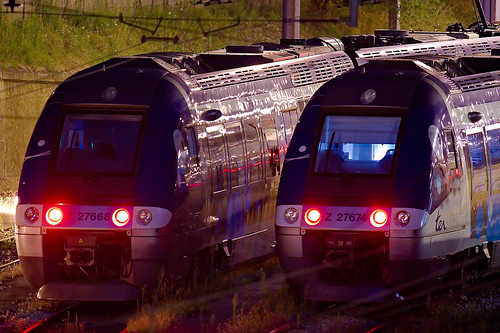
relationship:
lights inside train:
[371, 143, 395, 161] [272, 52, 499, 308]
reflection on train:
[188, 131, 279, 183] [272, 52, 499, 308]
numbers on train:
[78, 212, 110, 221] [11, 16, 497, 310]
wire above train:
[16, 8, 348, 35] [11, 16, 497, 310]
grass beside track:
[4, 10, 54, 245] [64, 266, 413, 331]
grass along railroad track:
[0, 0, 477, 59] [0, 236, 499, 333]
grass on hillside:
[127, 263, 306, 331] [2, 2, 497, 70]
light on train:
[362, 205, 395, 234] [272, 52, 499, 308]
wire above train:
[16, 8, 348, 35] [50, 34, 430, 323]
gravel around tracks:
[409, 290, 499, 329] [248, 276, 496, 326]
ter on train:
[431, 205, 456, 235] [272, 52, 499, 308]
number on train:
[320, 206, 370, 226] [271, 61, 496, 250]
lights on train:
[224, 153, 432, 265] [248, 45, 475, 321]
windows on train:
[305, 113, 430, 184] [216, 46, 488, 234]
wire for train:
[16, 8, 348, 35] [62, 27, 350, 279]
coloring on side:
[221, 183, 256, 233] [176, 74, 278, 254]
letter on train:
[321, 209, 336, 228] [285, 72, 488, 277]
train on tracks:
[11, 20, 500, 310] [7, 299, 177, 331]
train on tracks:
[11, 20, 500, 310] [247, 284, 468, 317]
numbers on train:
[73, 206, 113, 225] [11, 16, 497, 310]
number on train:
[338, 213, 367, 223] [297, 57, 472, 252]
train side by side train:
[11, 16, 497, 310] [271, 53, 498, 285]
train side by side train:
[271, 53, 498, 285] [11, 16, 497, 310]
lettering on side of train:
[433, 207, 448, 237] [272, 52, 499, 308]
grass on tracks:
[0, 0, 477, 59] [22, 302, 165, 331]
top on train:
[160, 47, 277, 77] [11, 16, 497, 310]